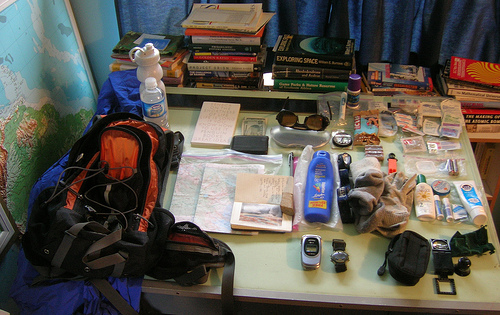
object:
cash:
[241, 119, 265, 136]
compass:
[431, 238, 460, 294]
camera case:
[377, 229, 431, 286]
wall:
[0, 2, 98, 247]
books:
[196, 82, 259, 90]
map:
[1, 1, 96, 234]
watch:
[330, 237, 350, 273]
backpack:
[20, 114, 237, 315]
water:
[139, 80, 180, 130]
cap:
[144, 76, 159, 89]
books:
[188, 43, 261, 52]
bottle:
[303, 150, 335, 224]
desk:
[73, 52, 500, 315]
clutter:
[103, 34, 467, 291]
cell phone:
[300, 234, 322, 272]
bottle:
[139, 76, 170, 128]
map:
[389, 64, 426, 83]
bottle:
[345, 73, 363, 110]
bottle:
[413, 173, 437, 221]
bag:
[377, 230, 431, 287]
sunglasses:
[275, 96, 334, 132]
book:
[274, 50, 354, 71]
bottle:
[129, 42, 169, 128]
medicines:
[399, 135, 428, 153]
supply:
[452, 180, 488, 227]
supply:
[413, 173, 437, 222]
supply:
[387, 152, 399, 175]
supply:
[352, 108, 381, 147]